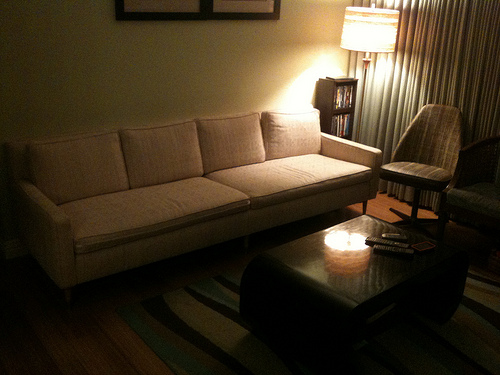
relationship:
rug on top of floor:
[114, 264, 498, 374] [1, 189, 499, 374]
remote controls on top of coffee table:
[366, 231, 436, 257] [238, 213, 467, 357]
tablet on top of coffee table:
[412, 240, 434, 253] [238, 213, 467, 357]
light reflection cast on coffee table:
[323, 228, 374, 276] [238, 213, 467, 357]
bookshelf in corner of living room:
[315, 75, 357, 144] [1, 1, 498, 374]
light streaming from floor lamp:
[259, 47, 440, 221] [338, 5, 401, 143]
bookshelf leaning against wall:
[315, 75, 357, 144] [1, 1, 349, 249]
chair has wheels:
[379, 101, 464, 241] [387, 205, 448, 241]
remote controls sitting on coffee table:
[366, 243, 417, 257] [238, 213, 467, 357]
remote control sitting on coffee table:
[364, 234, 409, 249] [238, 213, 467, 357]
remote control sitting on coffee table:
[382, 231, 408, 241] [238, 213, 467, 357]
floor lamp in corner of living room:
[338, 5, 401, 143] [1, 1, 498, 374]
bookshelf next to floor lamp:
[315, 75, 357, 144] [338, 5, 401, 143]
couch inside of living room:
[4, 103, 382, 301] [1, 1, 498, 374]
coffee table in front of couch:
[238, 213, 467, 357] [4, 103, 382, 301]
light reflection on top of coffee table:
[323, 228, 374, 276] [238, 213, 467, 357]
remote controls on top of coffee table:
[366, 243, 417, 257] [238, 213, 467, 357]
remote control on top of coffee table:
[364, 234, 409, 249] [238, 213, 467, 357]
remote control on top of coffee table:
[382, 231, 408, 241] [238, 213, 467, 357]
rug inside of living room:
[114, 264, 498, 374] [1, 1, 498, 374]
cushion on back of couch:
[26, 129, 129, 206] [4, 103, 382, 301]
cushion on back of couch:
[121, 118, 205, 187] [4, 103, 382, 301]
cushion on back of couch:
[197, 111, 266, 174] [4, 103, 382, 301]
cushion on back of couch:
[260, 106, 320, 160] [4, 103, 382, 301]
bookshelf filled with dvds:
[315, 75, 357, 144] [331, 84, 353, 110]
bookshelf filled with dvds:
[315, 75, 357, 144] [330, 114, 351, 137]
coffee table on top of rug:
[238, 213, 467, 357] [114, 264, 498, 374]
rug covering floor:
[114, 264, 498, 374] [1, 189, 499, 374]